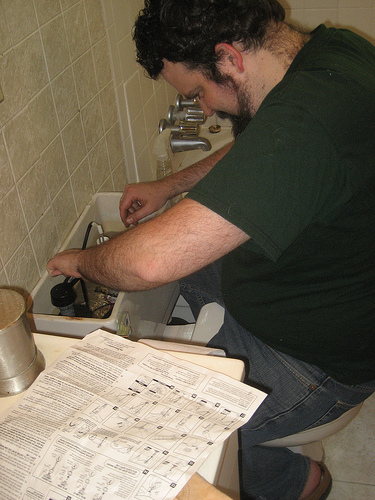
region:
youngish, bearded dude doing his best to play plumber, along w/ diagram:
[0, 0, 374, 499]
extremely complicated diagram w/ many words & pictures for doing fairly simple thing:
[0, 320, 279, 498]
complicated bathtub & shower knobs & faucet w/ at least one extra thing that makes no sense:
[152, 87, 219, 156]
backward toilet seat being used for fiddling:
[242, 389, 362, 467]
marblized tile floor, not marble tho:
[295, 390, 374, 498]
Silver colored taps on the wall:
[153, 88, 214, 154]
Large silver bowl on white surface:
[0, 282, 39, 400]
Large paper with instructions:
[1, 327, 269, 498]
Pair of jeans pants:
[180, 257, 371, 499]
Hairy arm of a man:
[43, 195, 251, 292]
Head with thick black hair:
[120, 0, 313, 138]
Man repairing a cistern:
[30, 181, 181, 340]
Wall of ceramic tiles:
[0, 0, 207, 291]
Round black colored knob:
[46, 280, 80, 307]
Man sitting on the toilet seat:
[48, 0, 374, 498]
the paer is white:
[53, 341, 255, 497]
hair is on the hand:
[88, 236, 183, 275]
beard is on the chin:
[218, 82, 258, 115]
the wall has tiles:
[31, 84, 123, 210]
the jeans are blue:
[261, 359, 343, 420]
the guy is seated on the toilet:
[100, 6, 372, 436]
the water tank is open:
[76, 197, 138, 320]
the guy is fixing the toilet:
[63, 14, 371, 417]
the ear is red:
[214, 42, 249, 68]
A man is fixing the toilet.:
[47, 193, 168, 316]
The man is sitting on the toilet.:
[163, 164, 352, 436]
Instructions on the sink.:
[64, 348, 199, 465]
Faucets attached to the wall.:
[154, 100, 201, 154]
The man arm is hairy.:
[78, 240, 131, 275]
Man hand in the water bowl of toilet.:
[39, 214, 160, 310]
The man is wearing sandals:
[308, 452, 335, 487]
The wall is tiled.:
[13, 45, 114, 173]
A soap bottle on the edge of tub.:
[144, 136, 186, 192]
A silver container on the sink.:
[5, 292, 44, 388]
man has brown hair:
[133, 11, 329, 68]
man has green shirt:
[198, 38, 373, 376]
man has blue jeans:
[198, 325, 343, 485]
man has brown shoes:
[305, 465, 351, 498]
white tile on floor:
[323, 445, 369, 496]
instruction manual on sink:
[4, 338, 275, 498]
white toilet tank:
[44, 187, 167, 339]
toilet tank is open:
[31, 183, 190, 329]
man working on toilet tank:
[57, 191, 196, 360]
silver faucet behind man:
[142, 91, 215, 153]